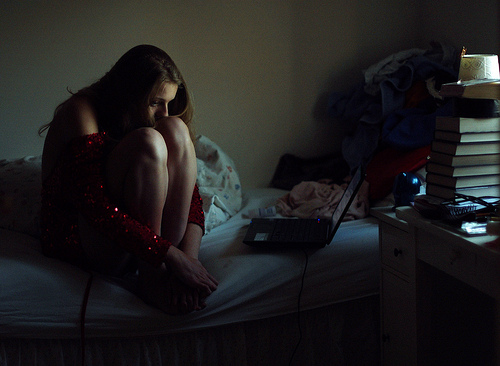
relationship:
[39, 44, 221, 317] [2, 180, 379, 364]
woman sitting on a bed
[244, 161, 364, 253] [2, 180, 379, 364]
laptop sitting on a bed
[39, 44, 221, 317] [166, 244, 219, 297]
woman's right hand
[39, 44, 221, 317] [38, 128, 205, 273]
woman's wearing a red sequined blouse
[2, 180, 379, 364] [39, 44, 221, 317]
bed of woman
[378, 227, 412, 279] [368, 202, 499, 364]
drawer of wooden desk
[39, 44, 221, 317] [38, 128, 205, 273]
woman in a red dress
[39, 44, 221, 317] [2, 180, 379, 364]
woman sitting on her bed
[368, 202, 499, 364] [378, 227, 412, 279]
white cabinet with a drawer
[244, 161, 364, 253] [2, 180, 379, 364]
laptop sitting on bed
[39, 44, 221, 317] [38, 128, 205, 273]
woman sitting in a red sequined dress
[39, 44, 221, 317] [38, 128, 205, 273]
woman wearing a red sequined blouse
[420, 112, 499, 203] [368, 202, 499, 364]
stack of books on wooden desk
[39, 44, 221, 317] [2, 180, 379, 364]
woman sitting on bed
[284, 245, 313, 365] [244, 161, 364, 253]
black wire from laptop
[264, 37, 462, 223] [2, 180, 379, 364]
pile of clothes at end of bed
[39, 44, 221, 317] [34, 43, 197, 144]
woman who has long brown hair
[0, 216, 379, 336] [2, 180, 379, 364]
edge of bed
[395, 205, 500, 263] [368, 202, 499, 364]
edge of a table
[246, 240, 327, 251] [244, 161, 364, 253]
edge of a laptop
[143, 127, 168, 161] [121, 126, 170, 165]
part of her knee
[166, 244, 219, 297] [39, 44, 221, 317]
hand of woman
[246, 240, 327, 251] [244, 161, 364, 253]
edge of laptop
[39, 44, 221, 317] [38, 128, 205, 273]
woman wearing a red dress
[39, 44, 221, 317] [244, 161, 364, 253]
woman in front of her laptop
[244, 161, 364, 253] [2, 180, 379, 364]
laptop on top of bed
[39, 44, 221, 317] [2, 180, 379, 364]
woman on her bed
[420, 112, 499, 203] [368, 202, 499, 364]
books on top of wooden desk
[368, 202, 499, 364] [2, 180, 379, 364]
wooden desk next to bed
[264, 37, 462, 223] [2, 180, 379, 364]
pile of clothes on bed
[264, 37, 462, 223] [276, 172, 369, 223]
messy pile of clothes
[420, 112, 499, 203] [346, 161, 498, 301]
large pile of hardcover books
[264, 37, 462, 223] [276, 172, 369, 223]
pile of clothing and clothes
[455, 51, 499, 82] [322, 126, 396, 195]
top half of a cream colored lamp shade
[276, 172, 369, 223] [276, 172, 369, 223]
clothes are clothes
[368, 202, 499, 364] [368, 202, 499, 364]
part of a wooden desk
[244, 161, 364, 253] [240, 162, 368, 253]
part of a laptop